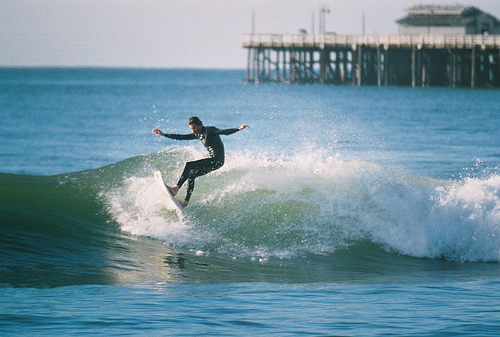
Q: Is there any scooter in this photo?
A: No, there are no scooters.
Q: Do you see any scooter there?
A: No, there are no scooters.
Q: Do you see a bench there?
A: No, there are no benches.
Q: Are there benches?
A: No, there are no benches.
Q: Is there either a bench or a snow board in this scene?
A: No, there are no benches or snowboards.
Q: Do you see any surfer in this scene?
A: Yes, there is a surfer.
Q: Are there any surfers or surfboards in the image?
A: Yes, there is a surfer.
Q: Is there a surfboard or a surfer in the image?
A: Yes, there is a surfer.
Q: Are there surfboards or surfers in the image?
A: Yes, there is a surfer.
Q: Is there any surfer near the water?
A: Yes, there is a surfer near the water.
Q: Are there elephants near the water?
A: No, there is a surfer near the water.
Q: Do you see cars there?
A: No, there are no cars.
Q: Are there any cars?
A: No, there are no cars.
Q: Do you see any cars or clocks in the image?
A: No, there are no cars or clocks.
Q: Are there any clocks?
A: No, there are no clocks.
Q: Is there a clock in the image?
A: No, there are no clocks.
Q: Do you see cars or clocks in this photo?
A: No, there are no clocks or cars.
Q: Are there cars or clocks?
A: No, there are no clocks or cars.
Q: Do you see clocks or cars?
A: No, there are no clocks or cars.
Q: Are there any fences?
A: Yes, there is a fence.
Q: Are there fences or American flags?
A: Yes, there is a fence.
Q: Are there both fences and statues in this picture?
A: No, there is a fence but no statues.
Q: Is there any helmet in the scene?
A: No, there are no helmets.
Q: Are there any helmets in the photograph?
A: No, there are no helmets.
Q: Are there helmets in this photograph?
A: No, there are no helmets.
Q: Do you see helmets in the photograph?
A: No, there are no helmets.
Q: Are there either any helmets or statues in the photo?
A: No, there are no helmets or statues.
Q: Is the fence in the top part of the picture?
A: Yes, the fence is in the top of the image.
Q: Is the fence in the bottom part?
A: No, the fence is in the top of the image.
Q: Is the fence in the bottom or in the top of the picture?
A: The fence is in the top of the image.